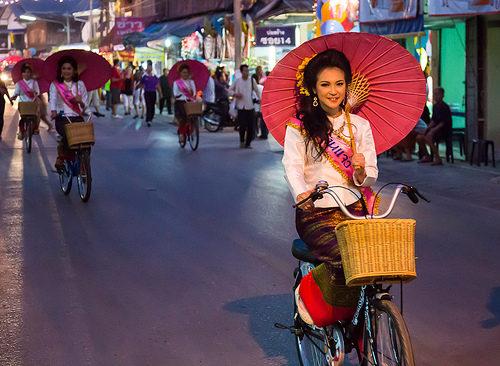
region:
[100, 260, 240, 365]
The ground is gray.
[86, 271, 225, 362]
The ground is made of asphalt.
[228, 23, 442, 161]
The umbrella is red.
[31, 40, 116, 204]
The person is on a bike.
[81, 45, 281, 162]
People are in the background.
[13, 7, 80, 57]
A street lamp.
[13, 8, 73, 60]
The street lamp is on.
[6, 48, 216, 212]
Other people are on bikes.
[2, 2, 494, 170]
Buildings are in the background.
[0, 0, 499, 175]
Buildings are lining the street.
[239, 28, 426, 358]
Woman riding a bike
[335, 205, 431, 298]
Basket on front of bike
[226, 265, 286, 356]
Shadow on the pavement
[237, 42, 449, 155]
The woman is holding an umbrella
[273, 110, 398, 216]
Woman wearing a sash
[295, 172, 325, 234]
Woman holding a handlebar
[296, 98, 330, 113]
Woman wearing earrings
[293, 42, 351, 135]
The woman has dark hair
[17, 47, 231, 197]
Group of women wearing bikes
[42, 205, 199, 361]
The pavement is flat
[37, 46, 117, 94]
A red paper umbrella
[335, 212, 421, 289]
A brown wicker basket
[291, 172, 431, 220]
Bicycle handle bars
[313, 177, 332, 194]
A silver bicycle bell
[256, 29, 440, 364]
A girl riding a bicycle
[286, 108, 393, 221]
A pink sash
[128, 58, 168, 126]
A person in a blue shirt walking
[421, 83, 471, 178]
A person sitting on a bench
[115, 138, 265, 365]
A section of road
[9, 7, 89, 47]
A lite up street light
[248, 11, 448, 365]
woman in foreground riding bicycle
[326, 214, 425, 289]
basket on front bicycle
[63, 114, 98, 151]
basket on second bicycle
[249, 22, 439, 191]
pink umbrella being held by first girl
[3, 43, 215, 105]
pink umbrellas in the background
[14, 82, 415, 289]
woven baskets on four bicycles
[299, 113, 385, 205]
pink sash with blue writing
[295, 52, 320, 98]
yellow flowers in girl's hair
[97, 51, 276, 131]
people walking down the street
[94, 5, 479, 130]
lit up storefronts on the street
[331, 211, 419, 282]
the basket of a bicycle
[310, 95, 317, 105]
the earring of a woman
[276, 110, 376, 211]
a white shirt on a woman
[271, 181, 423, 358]
a bicycle on the street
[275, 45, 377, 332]
a woman on a bicycle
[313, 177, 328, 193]
a bell on the bicycle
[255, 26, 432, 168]
a umbrella in the woman's hand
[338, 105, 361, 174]
the handle of an umbrella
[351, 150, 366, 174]
a hand of the woman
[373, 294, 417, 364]
a tire of a bicycle